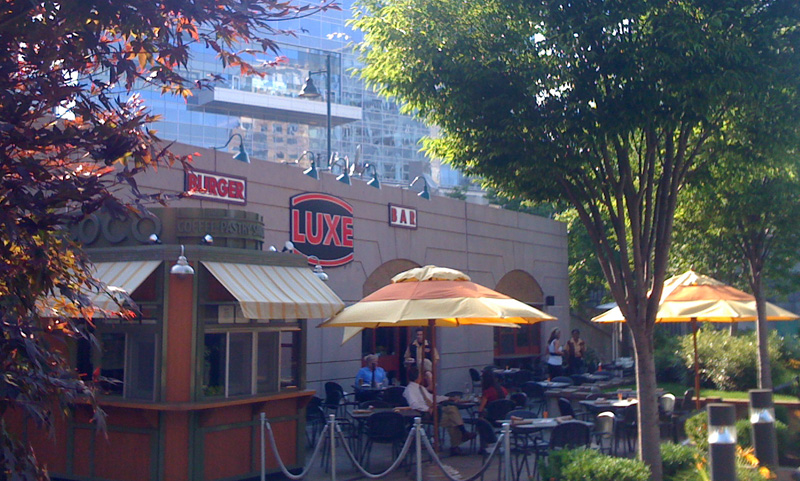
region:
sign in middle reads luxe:
[272, 179, 365, 272]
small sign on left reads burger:
[175, 155, 253, 219]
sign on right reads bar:
[380, 197, 420, 238]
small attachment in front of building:
[25, 185, 357, 478]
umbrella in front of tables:
[322, 244, 562, 479]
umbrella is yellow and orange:
[317, 254, 562, 345]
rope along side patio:
[243, 401, 507, 478]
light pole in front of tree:
[699, 390, 750, 479]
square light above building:
[180, 64, 365, 141]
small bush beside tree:
[540, 428, 653, 479]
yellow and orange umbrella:
[341, 237, 543, 334]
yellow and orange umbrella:
[584, 261, 756, 322]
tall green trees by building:
[399, 9, 795, 244]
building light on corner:
[157, 251, 209, 280]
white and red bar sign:
[387, 195, 433, 243]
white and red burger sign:
[172, 168, 269, 203]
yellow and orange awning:
[180, 256, 345, 323]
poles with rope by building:
[236, 413, 429, 474]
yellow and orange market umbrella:
[314, 262, 557, 335]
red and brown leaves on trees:
[2, 3, 343, 469]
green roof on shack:
[59, 200, 313, 269]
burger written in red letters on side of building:
[180, 168, 248, 202]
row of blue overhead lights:
[211, 131, 436, 201]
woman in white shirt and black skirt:
[545, 323, 566, 375]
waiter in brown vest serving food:
[402, 329, 437, 379]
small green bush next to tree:
[533, 445, 651, 479]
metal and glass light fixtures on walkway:
[702, 398, 738, 479]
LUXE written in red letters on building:
[284, 187, 362, 269]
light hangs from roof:
[211, 129, 252, 167]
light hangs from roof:
[287, 145, 322, 179]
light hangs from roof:
[327, 152, 354, 185]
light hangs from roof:
[359, 160, 384, 190]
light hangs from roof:
[403, 171, 431, 203]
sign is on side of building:
[286, 188, 359, 269]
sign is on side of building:
[383, 201, 423, 230]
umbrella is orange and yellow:
[317, 259, 555, 470]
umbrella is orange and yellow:
[590, 266, 796, 426]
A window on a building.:
[380, 158, 399, 180]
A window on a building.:
[381, 118, 397, 129]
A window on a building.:
[287, 131, 304, 145]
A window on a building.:
[246, 128, 264, 140]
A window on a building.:
[165, 121, 182, 138]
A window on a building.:
[135, 98, 151, 109]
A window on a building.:
[278, 134, 289, 145]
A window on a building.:
[381, 157, 401, 166]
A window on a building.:
[326, 42, 332, 59]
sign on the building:
[239, 169, 409, 323]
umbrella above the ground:
[317, 243, 533, 363]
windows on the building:
[173, 289, 320, 422]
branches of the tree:
[561, 217, 707, 307]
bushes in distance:
[666, 299, 779, 403]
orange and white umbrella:
[592, 250, 787, 358]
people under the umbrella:
[344, 311, 573, 460]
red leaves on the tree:
[10, 11, 237, 303]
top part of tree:
[338, 24, 717, 226]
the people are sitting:
[362, 358, 524, 426]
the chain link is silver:
[337, 425, 426, 478]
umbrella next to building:
[319, 234, 556, 358]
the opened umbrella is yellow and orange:
[317, 264, 559, 477]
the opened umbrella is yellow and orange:
[589, 263, 798, 410]